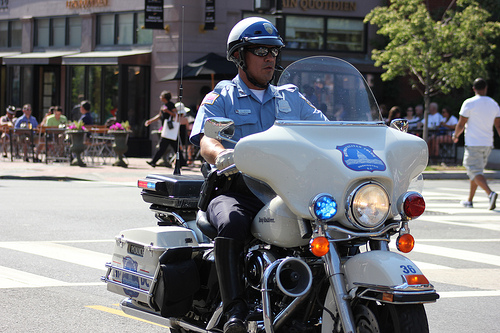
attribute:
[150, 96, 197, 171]
person — carrying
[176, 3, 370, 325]
officer — wearing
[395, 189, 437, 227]
light — red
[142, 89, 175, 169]
man — dressed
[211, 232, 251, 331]
boot — black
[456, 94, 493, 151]
shirt — white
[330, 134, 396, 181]
shield — police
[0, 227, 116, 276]
line — white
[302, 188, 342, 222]
light — blue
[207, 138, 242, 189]
glove — white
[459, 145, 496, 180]
shorts — brown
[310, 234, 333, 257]
orange headlight — broken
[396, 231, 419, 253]
orange headlight — broken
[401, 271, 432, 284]
orange headlight — broken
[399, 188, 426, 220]
orange headlight — broken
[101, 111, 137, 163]
planter — tall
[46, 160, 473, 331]
bike — white, police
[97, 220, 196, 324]
container — white